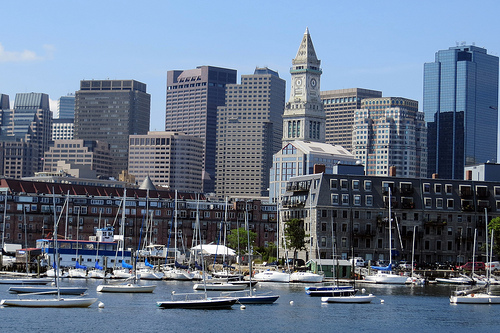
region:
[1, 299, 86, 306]
boat is next to boat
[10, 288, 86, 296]
boat is next to boat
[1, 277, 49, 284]
boat is next to boat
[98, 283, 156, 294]
boat is next to boat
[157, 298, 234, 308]
boat is next to boat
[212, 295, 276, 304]
boat is next to boat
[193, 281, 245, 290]
boat is next to boat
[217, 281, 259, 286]
boat is next to boat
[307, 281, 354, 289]
boat is next to boat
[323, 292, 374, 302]
boat is next to boat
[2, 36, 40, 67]
The small cloud in the sky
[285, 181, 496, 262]
The low building near the water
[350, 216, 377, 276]
The palm trees near the water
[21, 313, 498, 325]
The open ocean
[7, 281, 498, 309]
The ocean with all the boats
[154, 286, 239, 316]
The boat with brown bottom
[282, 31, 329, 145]
The building with the point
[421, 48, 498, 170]
The building with reflective outsides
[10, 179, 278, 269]
The small brown building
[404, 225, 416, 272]
The pole coming off the boat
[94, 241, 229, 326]
Boats in the water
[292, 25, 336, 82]
Steeple on the tower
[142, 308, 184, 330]
The water is flat no waves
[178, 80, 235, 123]
Windows on the side of the building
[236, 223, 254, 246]
Small tree beside the building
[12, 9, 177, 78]
The sky is clear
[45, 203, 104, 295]
Pole on the boat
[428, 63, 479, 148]
Light reflecting on side of building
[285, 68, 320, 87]
Clock on top of the tower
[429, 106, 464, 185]
Shadow on the building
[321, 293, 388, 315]
white sail boat on water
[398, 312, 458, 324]
blue area on water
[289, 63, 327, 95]
two clocks on tall building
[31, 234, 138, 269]
blue white and red boat in water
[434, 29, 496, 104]
tall silver building on right of photo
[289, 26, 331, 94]
pointed tower on top of building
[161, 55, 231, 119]
tall brown building in middle of photo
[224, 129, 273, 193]
tan building with many windows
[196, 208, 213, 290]
tall pole used to hold sails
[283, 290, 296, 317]
white floating object in water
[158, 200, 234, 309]
A sail boat in the water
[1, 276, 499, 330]
A body of water full of boats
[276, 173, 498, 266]
A building near the water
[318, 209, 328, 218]
A window on the building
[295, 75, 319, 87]
Clocks on the tower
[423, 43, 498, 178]
A reflective building in the city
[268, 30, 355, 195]
A clocktower in the city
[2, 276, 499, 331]
The water is calm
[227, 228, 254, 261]
A tree by the boats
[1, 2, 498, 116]
The blue sky above the buildings